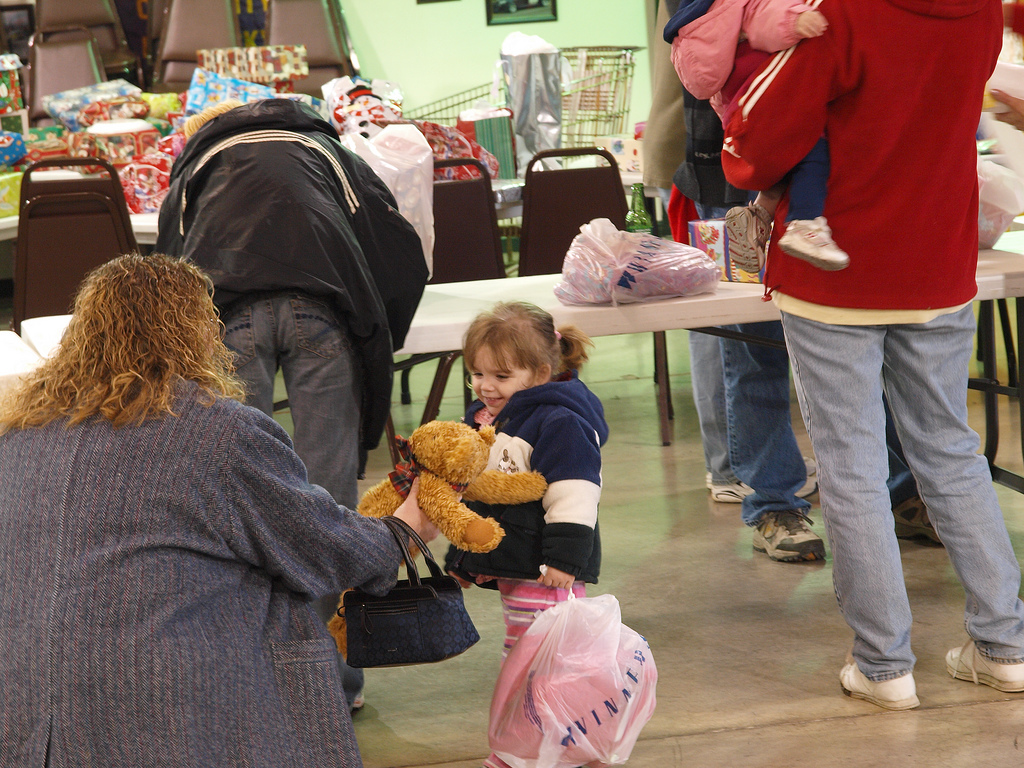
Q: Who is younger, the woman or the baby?
A: The baby is younger than the woman.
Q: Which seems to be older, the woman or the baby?
A: The woman is older than the baby.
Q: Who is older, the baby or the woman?
A: The woman is older than the baby.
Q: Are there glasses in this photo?
A: No, there are no glasses.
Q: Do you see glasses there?
A: No, there are no glasses.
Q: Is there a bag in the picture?
A: Yes, there is a bag.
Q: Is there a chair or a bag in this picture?
A: Yes, there is a bag.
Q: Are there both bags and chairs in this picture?
A: Yes, there are both a bag and a chair.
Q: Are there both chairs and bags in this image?
A: Yes, there are both a bag and a chair.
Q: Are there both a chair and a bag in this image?
A: Yes, there are both a bag and a chair.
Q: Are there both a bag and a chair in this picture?
A: Yes, there are both a bag and a chair.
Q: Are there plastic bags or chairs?
A: Yes, there is a plastic bag.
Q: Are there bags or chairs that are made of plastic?
A: Yes, the bag is made of plastic.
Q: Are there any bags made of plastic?
A: Yes, there is a bag that is made of plastic.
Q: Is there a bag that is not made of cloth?
A: Yes, there is a bag that is made of plastic.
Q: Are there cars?
A: No, there are no cars.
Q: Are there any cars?
A: No, there are no cars.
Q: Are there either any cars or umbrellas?
A: No, there are no cars or umbrellas.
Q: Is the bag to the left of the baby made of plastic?
A: Yes, the bag is made of plastic.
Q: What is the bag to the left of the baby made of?
A: The bag is made of plastic.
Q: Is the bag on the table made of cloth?
A: No, the bag is made of plastic.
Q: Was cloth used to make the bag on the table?
A: No, the bag is made of plastic.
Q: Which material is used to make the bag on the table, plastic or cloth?
A: The bag is made of plastic.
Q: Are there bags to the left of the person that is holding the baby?
A: Yes, there is a bag to the left of the person.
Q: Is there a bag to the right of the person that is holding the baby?
A: No, the bag is to the left of the person.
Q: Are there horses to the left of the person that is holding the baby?
A: No, there is a bag to the left of the person.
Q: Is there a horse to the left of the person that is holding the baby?
A: No, there is a bag to the left of the person.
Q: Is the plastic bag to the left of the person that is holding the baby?
A: Yes, the bag is to the left of the person.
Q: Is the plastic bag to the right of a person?
A: No, the bag is to the left of a person.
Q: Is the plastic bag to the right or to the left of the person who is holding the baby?
A: The bag is to the left of the person.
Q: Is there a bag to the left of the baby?
A: Yes, there is a bag to the left of the baby.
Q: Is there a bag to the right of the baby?
A: No, the bag is to the left of the baby.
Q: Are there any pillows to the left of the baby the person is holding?
A: No, there is a bag to the left of the baby.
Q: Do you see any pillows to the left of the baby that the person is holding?
A: No, there is a bag to the left of the baby.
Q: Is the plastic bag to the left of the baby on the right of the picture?
A: Yes, the bag is to the left of the baby.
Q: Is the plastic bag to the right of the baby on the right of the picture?
A: No, the bag is to the left of the baby.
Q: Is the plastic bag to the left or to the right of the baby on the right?
A: The bag is to the left of the baby.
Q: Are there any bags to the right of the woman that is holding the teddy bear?
A: Yes, there is a bag to the right of the woman.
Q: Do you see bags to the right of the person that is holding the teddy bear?
A: Yes, there is a bag to the right of the woman.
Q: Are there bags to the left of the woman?
A: No, the bag is to the right of the woman.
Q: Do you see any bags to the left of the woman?
A: No, the bag is to the right of the woman.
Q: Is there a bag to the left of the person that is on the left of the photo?
A: No, the bag is to the right of the woman.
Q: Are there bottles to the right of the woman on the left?
A: No, there is a bag to the right of the woman.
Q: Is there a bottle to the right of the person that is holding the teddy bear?
A: No, there is a bag to the right of the woman.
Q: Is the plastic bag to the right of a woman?
A: Yes, the bag is to the right of a woman.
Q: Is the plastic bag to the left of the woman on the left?
A: No, the bag is to the right of the woman.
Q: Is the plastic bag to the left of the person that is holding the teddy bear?
A: No, the bag is to the right of the woman.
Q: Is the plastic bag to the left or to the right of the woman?
A: The bag is to the right of the woman.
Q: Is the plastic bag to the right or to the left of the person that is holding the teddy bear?
A: The bag is to the right of the woman.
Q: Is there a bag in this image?
A: Yes, there is a bag.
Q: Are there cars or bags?
A: Yes, there is a bag.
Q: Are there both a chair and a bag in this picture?
A: Yes, there are both a bag and a chair.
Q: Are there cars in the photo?
A: No, there are no cars.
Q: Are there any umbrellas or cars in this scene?
A: No, there are no cars or umbrellas.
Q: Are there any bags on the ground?
A: Yes, there is a bag on the ground.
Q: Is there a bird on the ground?
A: No, there is a bag on the ground.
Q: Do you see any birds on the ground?
A: No, there is a bag on the ground.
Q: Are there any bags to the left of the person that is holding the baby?
A: Yes, there is a bag to the left of the person.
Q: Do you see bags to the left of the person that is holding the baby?
A: Yes, there is a bag to the left of the person.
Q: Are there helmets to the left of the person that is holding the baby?
A: No, there is a bag to the left of the person.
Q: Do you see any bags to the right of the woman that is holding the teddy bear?
A: Yes, there is a bag to the right of the woman.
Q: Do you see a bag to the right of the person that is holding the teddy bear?
A: Yes, there is a bag to the right of the woman.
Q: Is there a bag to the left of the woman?
A: No, the bag is to the right of the woman.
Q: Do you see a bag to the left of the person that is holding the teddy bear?
A: No, the bag is to the right of the woman.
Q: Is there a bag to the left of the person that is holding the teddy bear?
A: No, the bag is to the right of the woman.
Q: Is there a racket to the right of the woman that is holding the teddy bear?
A: No, there is a bag to the right of the woman.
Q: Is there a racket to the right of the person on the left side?
A: No, there is a bag to the right of the woman.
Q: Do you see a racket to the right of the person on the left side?
A: No, there is a bag to the right of the woman.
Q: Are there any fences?
A: No, there are no fences.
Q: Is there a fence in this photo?
A: No, there are no fences.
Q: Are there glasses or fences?
A: No, there are no fences or glasses.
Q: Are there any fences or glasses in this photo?
A: No, there are no fences or glasses.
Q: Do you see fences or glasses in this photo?
A: No, there are no fences or glasses.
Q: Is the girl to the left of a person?
A: Yes, the girl is to the left of a person.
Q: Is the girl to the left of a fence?
A: No, the girl is to the left of a person.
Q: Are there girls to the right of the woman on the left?
A: Yes, there is a girl to the right of the woman.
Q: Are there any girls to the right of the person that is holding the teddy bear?
A: Yes, there is a girl to the right of the woman.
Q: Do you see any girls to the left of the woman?
A: No, the girl is to the right of the woman.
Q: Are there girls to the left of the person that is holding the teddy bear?
A: No, the girl is to the right of the woman.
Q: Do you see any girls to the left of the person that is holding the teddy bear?
A: No, the girl is to the right of the woman.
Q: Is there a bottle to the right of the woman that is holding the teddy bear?
A: No, there is a girl to the right of the woman.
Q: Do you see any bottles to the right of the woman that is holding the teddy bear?
A: No, there is a girl to the right of the woman.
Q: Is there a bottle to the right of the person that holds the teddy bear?
A: No, there is a girl to the right of the woman.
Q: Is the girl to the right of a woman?
A: Yes, the girl is to the right of a woman.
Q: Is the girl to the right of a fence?
A: No, the girl is to the right of a woman.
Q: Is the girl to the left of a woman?
A: No, the girl is to the right of a woman.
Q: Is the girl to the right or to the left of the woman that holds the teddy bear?
A: The girl is to the right of the woman.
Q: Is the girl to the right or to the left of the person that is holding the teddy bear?
A: The girl is to the right of the woman.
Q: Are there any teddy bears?
A: Yes, there is a teddy bear.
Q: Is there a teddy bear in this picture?
A: Yes, there is a teddy bear.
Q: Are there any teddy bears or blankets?
A: Yes, there is a teddy bear.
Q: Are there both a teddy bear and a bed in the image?
A: No, there is a teddy bear but no beds.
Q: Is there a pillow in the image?
A: No, there are no pillows.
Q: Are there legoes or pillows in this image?
A: No, there are no pillows or legoes.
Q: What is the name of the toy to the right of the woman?
A: The toy is a teddy bear.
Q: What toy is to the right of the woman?
A: The toy is a teddy bear.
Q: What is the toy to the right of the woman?
A: The toy is a teddy bear.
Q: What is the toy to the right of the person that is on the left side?
A: The toy is a teddy bear.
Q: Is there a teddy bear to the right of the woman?
A: Yes, there is a teddy bear to the right of the woman.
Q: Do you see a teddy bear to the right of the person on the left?
A: Yes, there is a teddy bear to the right of the woman.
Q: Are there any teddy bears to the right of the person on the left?
A: Yes, there is a teddy bear to the right of the woman.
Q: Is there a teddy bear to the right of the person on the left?
A: Yes, there is a teddy bear to the right of the woman.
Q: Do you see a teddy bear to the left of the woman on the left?
A: No, the teddy bear is to the right of the woman.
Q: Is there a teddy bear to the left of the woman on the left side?
A: No, the teddy bear is to the right of the woman.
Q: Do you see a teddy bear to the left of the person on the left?
A: No, the teddy bear is to the right of the woman.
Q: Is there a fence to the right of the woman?
A: No, there is a teddy bear to the right of the woman.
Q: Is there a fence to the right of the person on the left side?
A: No, there is a teddy bear to the right of the woman.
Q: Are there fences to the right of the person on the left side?
A: No, there is a teddy bear to the right of the woman.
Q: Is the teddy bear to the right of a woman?
A: Yes, the teddy bear is to the right of a woman.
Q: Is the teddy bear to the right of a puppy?
A: No, the teddy bear is to the right of a woman.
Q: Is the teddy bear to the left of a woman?
A: No, the teddy bear is to the right of a woman.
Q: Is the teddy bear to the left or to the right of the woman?
A: The teddy bear is to the right of the woman.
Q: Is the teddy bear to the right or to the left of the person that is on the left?
A: The teddy bear is to the right of the woman.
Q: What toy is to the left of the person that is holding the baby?
A: The toy is a teddy bear.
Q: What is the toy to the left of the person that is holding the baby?
A: The toy is a teddy bear.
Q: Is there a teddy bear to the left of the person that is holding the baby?
A: Yes, there is a teddy bear to the left of the person.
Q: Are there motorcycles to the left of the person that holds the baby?
A: No, there is a teddy bear to the left of the person.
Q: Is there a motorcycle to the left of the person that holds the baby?
A: No, there is a teddy bear to the left of the person.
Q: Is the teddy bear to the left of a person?
A: Yes, the teddy bear is to the left of a person.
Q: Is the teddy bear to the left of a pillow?
A: No, the teddy bear is to the left of a person.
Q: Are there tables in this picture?
A: Yes, there is a table.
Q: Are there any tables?
A: Yes, there is a table.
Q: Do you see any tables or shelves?
A: Yes, there is a table.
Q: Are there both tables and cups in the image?
A: No, there is a table but no cups.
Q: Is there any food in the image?
A: No, there is no food.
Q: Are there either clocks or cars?
A: No, there are no cars or clocks.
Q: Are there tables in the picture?
A: Yes, there is a table.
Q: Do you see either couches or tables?
A: Yes, there is a table.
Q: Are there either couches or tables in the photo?
A: Yes, there is a table.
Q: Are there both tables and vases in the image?
A: No, there is a table but no vases.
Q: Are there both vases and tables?
A: No, there is a table but no vases.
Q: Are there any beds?
A: No, there are no beds.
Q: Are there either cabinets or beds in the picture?
A: No, there are no beds or cabinets.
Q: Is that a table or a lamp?
A: That is a table.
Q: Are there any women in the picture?
A: Yes, there is a woman.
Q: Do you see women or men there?
A: Yes, there is a woman.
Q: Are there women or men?
A: Yes, there is a woman.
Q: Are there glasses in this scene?
A: No, there are no glasses.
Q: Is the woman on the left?
A: Yes, the woman is on the left of the image.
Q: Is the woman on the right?
A: No, the woman is on the left of the image.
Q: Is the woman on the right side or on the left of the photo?
A: The woman is on the left of the image.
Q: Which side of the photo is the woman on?
A: The woman is on the left of the image.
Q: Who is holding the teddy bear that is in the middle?
A: The woman is holding the teddy bear.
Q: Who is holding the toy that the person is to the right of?
A: The woman is holding the teddy bear.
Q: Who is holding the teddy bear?
A: The woman is holding the teddy bear.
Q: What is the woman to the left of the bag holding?
A: The woman is holding the teddy bear.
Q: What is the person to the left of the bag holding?
A: The woman is holding the teddy bear.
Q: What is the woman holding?
A: The woman is holding the teddy bear.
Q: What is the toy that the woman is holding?
A: The toy is a teddy bear.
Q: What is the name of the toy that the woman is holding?
A: The toy is a teddy bear.